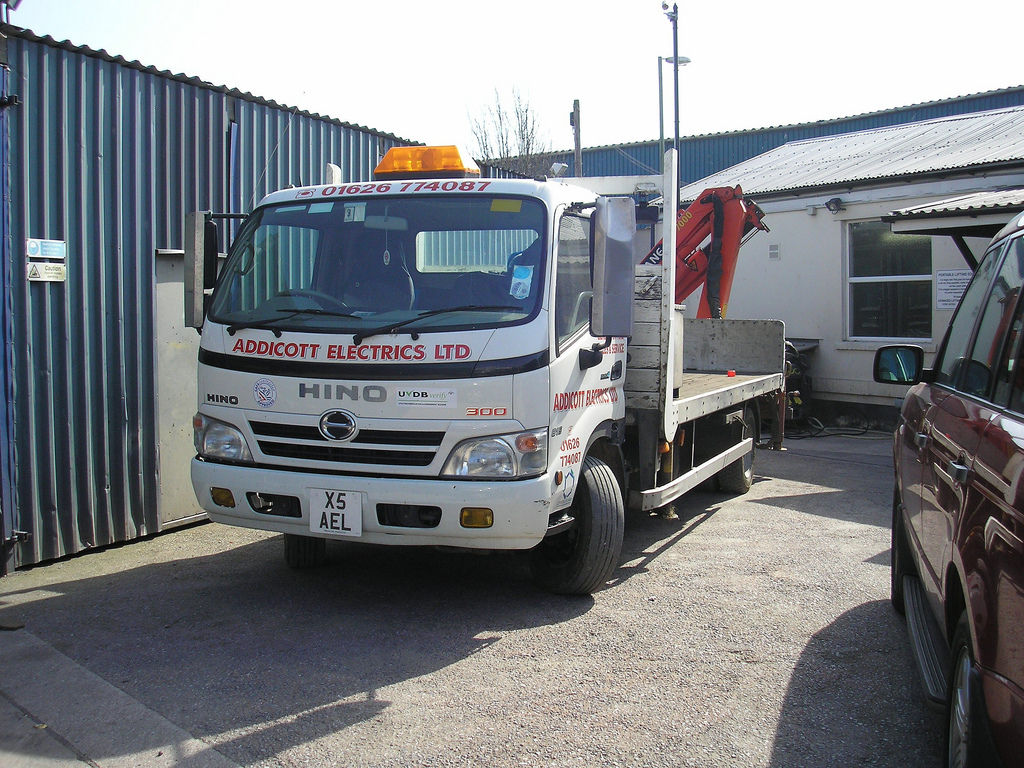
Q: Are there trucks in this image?
A: Yes, there is a truck.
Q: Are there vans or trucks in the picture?
A: Yes, there is a truck.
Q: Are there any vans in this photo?
A: No, there are no vans.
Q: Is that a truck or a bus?
A: That is a truck.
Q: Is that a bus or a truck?
A: That is a truck.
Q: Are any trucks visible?
A: Yes, there is a truck.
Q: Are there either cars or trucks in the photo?
A: Yes, there is a truck.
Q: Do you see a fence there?
A: No, there are no fences.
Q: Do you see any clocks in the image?
A: No, there are no clocks.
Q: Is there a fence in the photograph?
A: No, there are no fences.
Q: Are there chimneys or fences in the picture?
A: No, there are no fences or chimneys.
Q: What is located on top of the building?
A: The roof is on top of the building.